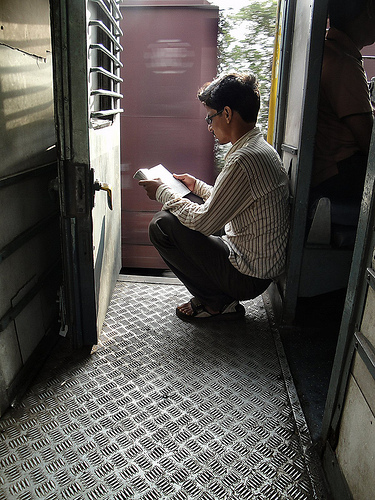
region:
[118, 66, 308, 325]
The man is crouching.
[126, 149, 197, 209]
The man is holding a book.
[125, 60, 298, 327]
The man is reading the book.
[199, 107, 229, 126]
The man wears eyeglasses.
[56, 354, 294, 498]
The floor is made of metal.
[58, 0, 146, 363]
The door is open.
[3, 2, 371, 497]
The man is on a train car.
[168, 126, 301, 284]
The man's shirt is striped.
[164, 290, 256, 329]
The man wears sandals.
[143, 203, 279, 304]
The man wears dark pants.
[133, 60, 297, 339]
Man is in a vehicle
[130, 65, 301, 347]
Man reads a book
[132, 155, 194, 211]
Book is open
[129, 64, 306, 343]
Man is crouched on a car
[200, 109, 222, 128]
Black glasses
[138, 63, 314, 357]
Man wears a long sleeve shirt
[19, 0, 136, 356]
Door of a vehicle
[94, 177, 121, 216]
Handle of door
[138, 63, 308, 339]
Man wears sandals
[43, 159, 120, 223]
Lock of door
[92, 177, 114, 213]
The latch to a door.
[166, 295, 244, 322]
A man's foot wearing sandal.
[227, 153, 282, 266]
A man's white striped shirt.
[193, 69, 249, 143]
the head of a man.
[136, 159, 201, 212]
A pair of hands holding a book.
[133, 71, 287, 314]
Man sitting in a "knees bent" position.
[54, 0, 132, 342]
One older, open door.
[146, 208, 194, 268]
Left knee of a person.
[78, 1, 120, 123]
Window area of an old door.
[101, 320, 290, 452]
rigid floor to doorway area.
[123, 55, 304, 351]
Poor man trying to better himself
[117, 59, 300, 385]
Man taking a long train ride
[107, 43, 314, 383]
Reading on the train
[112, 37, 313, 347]
Man on train with no seat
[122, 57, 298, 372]
Man sitting reading a book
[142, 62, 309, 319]
Man reading book traveling on train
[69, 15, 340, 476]
Worst seats on the train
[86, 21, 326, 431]
The train has poor safety standards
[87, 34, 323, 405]
Concentrating hard on book while traveling on train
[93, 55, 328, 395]
Man reading book with no notice of the world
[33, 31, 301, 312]
one person is seen.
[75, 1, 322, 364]
Train door is open.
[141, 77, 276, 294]
One man is sitting in the door step.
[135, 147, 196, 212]
Man is reading the book.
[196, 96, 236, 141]
Man is wearing black eyeglass.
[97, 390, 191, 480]
Floor is grey color.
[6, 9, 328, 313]
Day time picture.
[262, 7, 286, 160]
Yellow color handle of the door to get in and out.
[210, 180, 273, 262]
Man is wearing brown striped shirt.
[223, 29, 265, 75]
trees are green color.